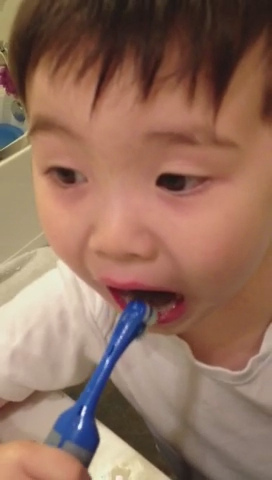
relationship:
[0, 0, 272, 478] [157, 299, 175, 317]
baby brushing his teeth teeth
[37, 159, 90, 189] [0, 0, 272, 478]
eye of baby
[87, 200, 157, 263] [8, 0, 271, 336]
nose of boy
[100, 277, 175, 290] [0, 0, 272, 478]
lip of baby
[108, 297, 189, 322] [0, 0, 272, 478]
lip of baby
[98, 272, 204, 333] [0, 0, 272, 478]
teeth of baby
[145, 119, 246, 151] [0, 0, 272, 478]
eye brows of baby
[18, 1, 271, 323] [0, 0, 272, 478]
head of baby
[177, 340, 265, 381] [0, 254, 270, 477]
collar on shirt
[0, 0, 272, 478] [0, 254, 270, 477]
baby wearing shirt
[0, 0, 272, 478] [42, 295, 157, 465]
baby holding toothbrush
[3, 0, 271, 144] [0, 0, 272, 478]
hair of baby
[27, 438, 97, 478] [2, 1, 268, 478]
finger of baby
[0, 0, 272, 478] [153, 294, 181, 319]
baby brushing teeth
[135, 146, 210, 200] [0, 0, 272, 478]
eye of baby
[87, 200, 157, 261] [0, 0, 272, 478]
nose of baby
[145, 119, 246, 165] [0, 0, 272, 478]
eye brows of baby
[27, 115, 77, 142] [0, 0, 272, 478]
eyebrow of baby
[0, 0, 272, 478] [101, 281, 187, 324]
baby brushing teeth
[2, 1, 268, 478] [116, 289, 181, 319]
baby brushing h teeth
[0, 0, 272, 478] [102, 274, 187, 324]
baby has an mouth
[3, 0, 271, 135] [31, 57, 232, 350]
hair of boy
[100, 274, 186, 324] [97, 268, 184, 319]
mouth of child